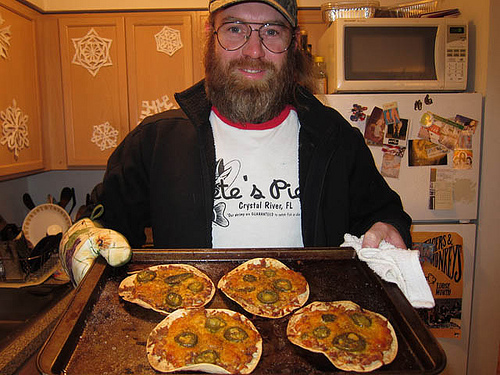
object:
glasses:
[213, 21, 296, 55]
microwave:
[317, 18, 468, 95]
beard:
[203, 54, 296, 123]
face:
[213, 1, 292, 81]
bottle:
[313, 57, 328, 95]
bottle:
[298, 30, 313, 94]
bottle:
[306, 44, 316, 94]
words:
[213, 178, 302, 217]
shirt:
[209, 104, 304, 249]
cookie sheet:
[117, 257, 397, 375]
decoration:
[154, 26, 184, 57]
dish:
[22, 203, 73, 247]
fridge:
[327, 92, 483, 375]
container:
[320, 0, 375, 27]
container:
[388, 0, 438, 18]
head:
[205, 0, 309, 88]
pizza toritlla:
[117, 264, 212, 312]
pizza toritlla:
[218, 260, 307, 316]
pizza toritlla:
[146, 308, 260, 374]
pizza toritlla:
[287, 302, 393, 371]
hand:
[59, 226, 132, 288]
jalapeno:
[223, 326, 248, 341]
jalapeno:
[204, 317, 226, 333]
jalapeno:
[174, 332, 197, 348]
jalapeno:
[195, 349, 218, 365]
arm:
[332, 107, 416, 222]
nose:
[242, 31, 265, 59]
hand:
[362, 221, 407, 250]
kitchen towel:
[340, 232, 436, 309]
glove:
[59, 204, 132, 291]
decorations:
[70, 27, 113, 77]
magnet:
[383, 101, 401, 124]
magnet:
[414, 100, 423, 111]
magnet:
[425, 94, 433, 105]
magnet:
[419, 113, 432, 128]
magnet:
[453, 150, 474, 169]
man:
[58, 0, 412, 289]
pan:
[35, 246, 449, 375]